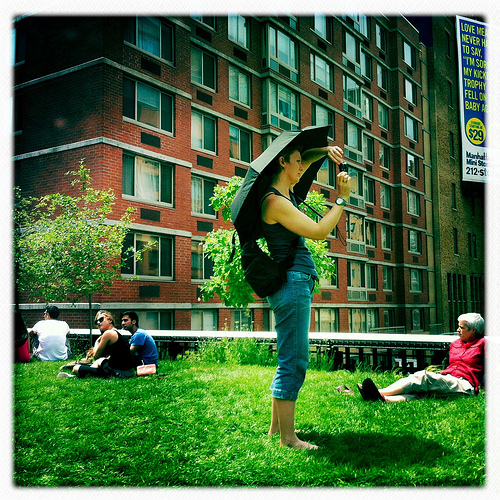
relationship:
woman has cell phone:
[255, 143, 352, 454] [339, 161, 349, 176]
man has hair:
[357, 310, 484, 409] [457, 310, 485, 335]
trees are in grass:
[17, 156, 158, 350] [14, 351, 487, 483]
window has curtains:
[120, 149, 180, 209] [124, 155, 173, 201]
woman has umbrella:
[255, 143, 352, 454] [225, 123, 333, 249]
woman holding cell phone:
[255, 143, 352, 454] [339, 161, 349, 176]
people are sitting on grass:
[55, 310, 137, 383] [14, 351, 487, 483]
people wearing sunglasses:
[55, 310, 137, 383] [91, 317, 108, 325]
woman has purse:
[255, 143, 352, 454] [229, 188, 305, 300]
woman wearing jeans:
[255, 143, 352, 454] [266, 269, 315, 403]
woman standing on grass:
[255, 143, 352, 454] [14, 351, 487, 483]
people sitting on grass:
[55, 310, 137, 383] [14, 351, 487, 483]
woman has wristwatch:
[255, 143, 352, 454] [333, 199, 347, 209]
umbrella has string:
[225, 123, 333, 249] [227, 227, 240, 263]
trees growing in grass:
[17, 156, 158, 350] [14, 351, 487, 483]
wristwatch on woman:
[333, 199, 347, 209] [255, 143, 352, 454]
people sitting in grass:
[55, 310, 137, 383] [14, 351, 487, 483]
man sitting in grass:
[28, 304, 73, 360] [14, 351, 487, 483]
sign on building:
[453, 14, 485, 187] [422, 13, 490, 336]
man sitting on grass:
[28, 304, 73, 360] [14, 351, 487, 483]